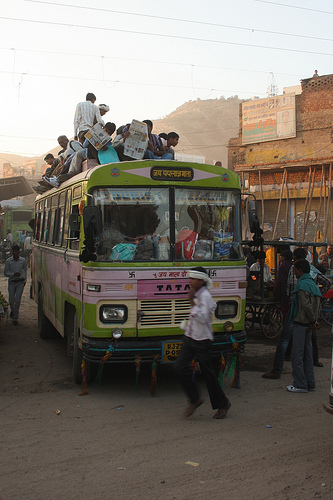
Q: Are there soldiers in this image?
A: No, there are no soldiers.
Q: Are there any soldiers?
A: No, there are no soldiers.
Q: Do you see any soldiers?
A: No, there are no soldiers.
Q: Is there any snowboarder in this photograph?
A: No, there are no snowboarders.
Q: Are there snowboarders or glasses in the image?
A: No, there are no snowboarders or glasses.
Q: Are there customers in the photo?
A: No, there are no customers.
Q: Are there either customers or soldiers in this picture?
A: No, there are no customers or soldiers.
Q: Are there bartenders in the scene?
A: No, there are no bartenders.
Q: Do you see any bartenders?
A: No, there are no bartenders.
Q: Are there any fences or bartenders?
A: No, there are no bartenders or fences.